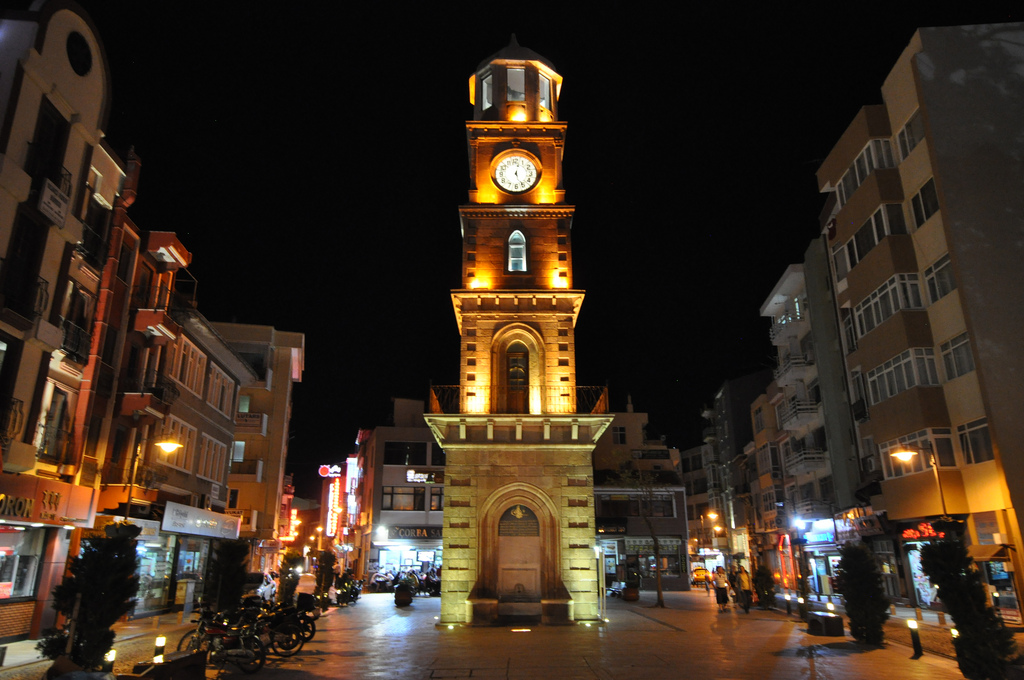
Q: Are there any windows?
A: Yes, there is a window.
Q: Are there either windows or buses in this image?
A: Yes, there is a window.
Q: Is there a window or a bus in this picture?
A: Yes, there is a window.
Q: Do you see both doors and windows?
A: Yes, there are both a window and a door.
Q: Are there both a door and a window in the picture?
A: Yes, there are both a window and a door.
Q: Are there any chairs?
A: No, there are no chairs.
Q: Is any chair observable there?
A: No, there are no chairs.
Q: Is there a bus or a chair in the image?
A: No, there are no chairs or buses.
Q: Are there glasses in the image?
A: No, there are no glasses.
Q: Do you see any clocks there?
A: Yes, there is a clock.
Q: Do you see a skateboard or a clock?
A: Yes, there is a clock.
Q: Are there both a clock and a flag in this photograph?
A: No, there is a clock but no flags.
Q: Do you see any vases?
A: No, there are no vases.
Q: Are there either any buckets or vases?
A: No, there are no vases or buckets.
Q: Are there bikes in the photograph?
A: Yes, there is a bike.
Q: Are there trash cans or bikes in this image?
A: Yes, there is a bike.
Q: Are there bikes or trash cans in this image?
A: Yes, there is a bike.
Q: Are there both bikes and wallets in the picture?
A: No, there is a bike but no wallets.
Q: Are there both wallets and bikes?
A: No, there is a bike but no wallets.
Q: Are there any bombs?
A: No, there are no bombs.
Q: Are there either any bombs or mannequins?
A: No, there are no bombs or mannequins.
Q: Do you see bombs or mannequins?
A: No, there are no bombs or mannequins.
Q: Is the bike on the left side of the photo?
A: Yes, the bike is on the left of the image.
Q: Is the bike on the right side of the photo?
A: No, the bike is on the left of the image.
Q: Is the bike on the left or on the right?
A: The bike is on the left of the image.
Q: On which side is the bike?
A: The bike is on the left of the image.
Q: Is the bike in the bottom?
A: Yes, the bike is in the bottom of the image.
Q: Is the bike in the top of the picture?
A: No, the bike is in the bottom of the image.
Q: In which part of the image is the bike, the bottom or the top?
A: The bike is in the bottom of the image.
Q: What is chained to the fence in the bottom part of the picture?
A: The bike is chained to the fence.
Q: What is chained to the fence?
A: The bike is chained to the fence.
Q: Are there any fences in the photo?
A: Yes, there is a fence.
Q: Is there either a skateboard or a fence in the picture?
A: Yes, there is a fence.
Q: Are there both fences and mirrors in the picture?
A: No, there is a fence but no mirrors.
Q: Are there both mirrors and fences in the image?
A: No, there is a fence but no mirrors.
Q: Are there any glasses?
A: No, there are no glasses.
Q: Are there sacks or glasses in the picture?
A: No, there are no glasses or sacks.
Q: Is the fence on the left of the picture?
A: Yes, the fence is on the left of the image.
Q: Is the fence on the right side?
A: No, the fence is on the left of the image.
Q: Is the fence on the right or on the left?
A: The fence is on the left of the image.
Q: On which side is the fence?
A: The fence is on the left of the image.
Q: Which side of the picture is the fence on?
A: The fence is on the left of the image.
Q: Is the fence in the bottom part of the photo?
A: Yes, the fence is in the bottom of the image.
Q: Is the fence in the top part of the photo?
A: No, the fence is in the bottom of the image.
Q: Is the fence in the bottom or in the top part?
A: The fence is in the bottom of the image.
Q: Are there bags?
A: No, there are no bags.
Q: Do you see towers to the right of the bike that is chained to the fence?
A: Yes, there is a tower to the right of the bike.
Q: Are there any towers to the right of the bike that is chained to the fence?
A: Yes, there is a tower to the right of the bike.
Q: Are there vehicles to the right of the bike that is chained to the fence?
A: No, there is a tower to the right of the bike.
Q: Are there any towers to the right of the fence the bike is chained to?
A: Yes, there is a tower to the right of the fence.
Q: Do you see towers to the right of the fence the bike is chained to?
A: Yes, there is a tower to the right of the fence.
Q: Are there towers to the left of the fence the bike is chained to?
A: No, the tower is to the right of the fence.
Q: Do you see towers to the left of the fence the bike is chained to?
A: No, the tower is to the right of the fence.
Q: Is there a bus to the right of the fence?
A: No, there is a tower to the right of the fence.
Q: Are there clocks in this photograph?
A: Yes, there is a clock.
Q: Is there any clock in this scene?
A: Yes, there is a clock.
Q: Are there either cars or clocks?
A: Yes, there is a clock.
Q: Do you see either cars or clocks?
A: Yes, there is a clock.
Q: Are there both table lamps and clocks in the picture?
A: No, there is a clock but no table lamps.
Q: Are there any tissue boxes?
A: No, there are no tissue boxes.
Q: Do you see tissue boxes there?
A: No, there are no tissue boxes.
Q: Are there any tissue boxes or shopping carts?
A: No, there are no tissue boxes or shopping carts.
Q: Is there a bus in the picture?
A: No, there are no buses.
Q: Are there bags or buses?
A: No, there are no buses or bags.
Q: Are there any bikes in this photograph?
A: Yes, there are bikes.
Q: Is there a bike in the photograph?
A: Yes, there are bikes.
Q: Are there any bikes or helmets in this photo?
A: Yes, there are bikes.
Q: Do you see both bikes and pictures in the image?
A: No, there are bikes but no pictures.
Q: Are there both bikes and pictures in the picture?
A: No, there are bikes but no pictures.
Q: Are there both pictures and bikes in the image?
A: No, there are bikes but no pictures.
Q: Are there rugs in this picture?
A: No, there are no rugs.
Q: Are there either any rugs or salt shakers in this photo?
A: No, there are no rugs or salt shakers.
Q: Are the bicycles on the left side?
A: Yes, the bicycles are on the left of the image.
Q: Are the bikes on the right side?
A: No, the bikes are on the left of the image.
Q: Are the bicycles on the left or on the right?
A: The bicycles are on the left of the image.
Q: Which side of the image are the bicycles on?
A: The bicycles are on the left of the image.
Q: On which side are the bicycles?
A: The bicycles are on the left of the image.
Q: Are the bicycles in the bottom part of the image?
A: Yes, the bicycles are in the bottom of the image.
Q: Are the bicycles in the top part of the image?
A: No, the bicycles are in the bottom of the image.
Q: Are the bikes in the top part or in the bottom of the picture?
A: The bikes are in the bottom of the image.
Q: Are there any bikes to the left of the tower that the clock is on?
A: Yes, there are bikes to the left of the tower.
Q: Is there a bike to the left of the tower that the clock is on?
A: Yes, there are bikes to the left of the tower.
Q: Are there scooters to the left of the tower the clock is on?
A: No, there are bikes to the left of the tower.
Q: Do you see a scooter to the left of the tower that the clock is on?
A: No, there are bikes to the left of the tower.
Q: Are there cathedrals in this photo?
A: No, there are no cathedrals.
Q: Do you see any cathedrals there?
A: No, there are no cathedrals.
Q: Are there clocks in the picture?
A: Yes, there is a clock.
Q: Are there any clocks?
A: Yes, there is a clock.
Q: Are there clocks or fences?
A: Yes, there is a clock.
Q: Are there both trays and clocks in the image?
A: No, there is a clock but no trays.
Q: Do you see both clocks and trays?
A: No, there is a clock but no trays.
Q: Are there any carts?
A: No, there are no carts.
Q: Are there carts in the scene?
A: No, there are no carts.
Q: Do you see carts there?
A: No, there are no carts.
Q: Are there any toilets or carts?
A: No, there are no carts or toilets.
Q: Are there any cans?
A: No, there are no cans.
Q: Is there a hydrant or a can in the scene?
A: No, there are no cans or fire hydrants.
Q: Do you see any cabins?
A: No, there are no cabins.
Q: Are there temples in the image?
A: No, there are no temples.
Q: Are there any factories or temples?
A: No, there are no temples or factories.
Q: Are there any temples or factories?
A: No, there are no temples or factories.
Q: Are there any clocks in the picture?
A: Yes, there is a clock.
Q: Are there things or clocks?
A: Yes, there is a clock.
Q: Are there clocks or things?
A: Yes, there is a clock.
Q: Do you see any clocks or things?
A: Yes, there is a clock.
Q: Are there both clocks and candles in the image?
A: No, there is a clock but no candles.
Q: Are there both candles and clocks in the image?
A: No, there is a clock but no candles.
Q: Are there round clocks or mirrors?
A: Yes, there is a round clock.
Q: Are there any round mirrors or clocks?
A: Yes, there is a round clock.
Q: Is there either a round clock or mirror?
A: Yes, there is a round clock.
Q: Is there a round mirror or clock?
A: Yes, there is a round clock.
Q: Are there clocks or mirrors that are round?
A: Yes, the clock is round.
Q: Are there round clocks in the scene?
A: Yes, there is a round clock.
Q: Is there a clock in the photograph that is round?
A: Yes, there is a clock that is round.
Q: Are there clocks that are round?
A: Yes, there is a clock that is round.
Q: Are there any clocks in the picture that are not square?
A: Yes, there is a round clock.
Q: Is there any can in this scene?
A: No, there are no cans.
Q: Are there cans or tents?
A: No, there are no cans or tents.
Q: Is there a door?
A: Yes, there is a door.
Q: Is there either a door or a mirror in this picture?
A: Yes, there is a door.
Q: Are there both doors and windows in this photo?
A: Yes, there are both a door and a window.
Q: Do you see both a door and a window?
A: Yes, there are both a door and a window.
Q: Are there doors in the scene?
A: Yes, there is a door.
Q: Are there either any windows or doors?
A: Yes, there is a door.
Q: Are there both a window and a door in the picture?
A: Yes, there are both a door and a window.